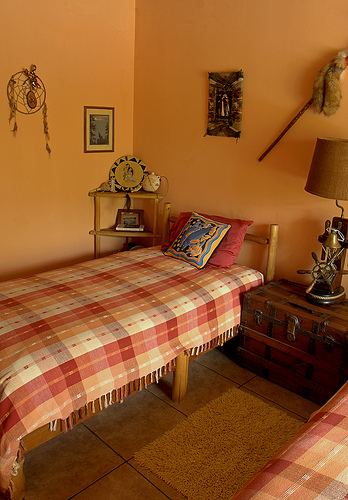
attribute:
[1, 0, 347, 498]
bedroom — neat, tidy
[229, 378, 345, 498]
blanket — plaid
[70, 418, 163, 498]
lines — black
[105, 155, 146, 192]
plate — native american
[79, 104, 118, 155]
print — wolf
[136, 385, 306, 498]
mat — white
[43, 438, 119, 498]
tiles — beige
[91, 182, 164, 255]
cabinet — small, wooden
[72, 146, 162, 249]
shelf — wood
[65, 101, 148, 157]
picture — framed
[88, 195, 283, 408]
twin bed — wood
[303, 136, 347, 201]
lampshade — brown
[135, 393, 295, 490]
rug — tan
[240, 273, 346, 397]
chest — wooden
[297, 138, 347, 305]
lamp — ship themed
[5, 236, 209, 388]
bed cover — plaid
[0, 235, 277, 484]
blanket — orange, red, white, plaid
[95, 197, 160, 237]
photo — framed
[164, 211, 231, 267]
throw pillow — multi-colored, patterned